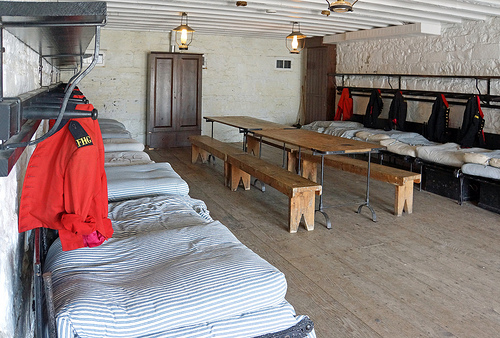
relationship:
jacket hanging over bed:
[15, 102, 112, 251] [32, 195, 296, 336]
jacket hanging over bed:
[17, 103, 112, 251] [301, 118, 361, 138]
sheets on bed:
[57, 200, 286, 333] [21, 189, 312, 337]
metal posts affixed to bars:
[337, 73, 347, 94] [329, 70, 499, 79]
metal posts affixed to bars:
[393, 71, 402, 93] [329, 70, 499, 79]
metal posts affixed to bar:
[482, 79, 495, 107] [336, 83, 499, 106]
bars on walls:
[329, 70, 499, 79] [1, 19, 498, 142]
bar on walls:
[336, 83, 499, 106] [1, 19, 498, 142]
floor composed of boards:
[232, 199, 499, 329] [148, 142, 498, 336]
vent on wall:
[86, 1, 483, 43] [61, 25, 303, 154]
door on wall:
[131, 39, 237, 159] [61, 25, 303, 154]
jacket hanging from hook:
[335, 88, 355, 122] [60, 105, 101, 123]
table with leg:
[183, 111, 383, 233] [308, 147, 335, 234]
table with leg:
[183, 111, 383, 233] [353, 145, 380, 224]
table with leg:
[183, 111, 383, 233] [241, 127, 271, 193]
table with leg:
[183, 111, 383, 233] [205, 115, 218, 162]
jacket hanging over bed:
[17, 103, 112, 251] [35, 194, 321, 334]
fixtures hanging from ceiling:
[169, 10, 311, 61] [71, 0, 498, 38]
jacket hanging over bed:
[15, 102, 112, 251] [43, 229, 308, 336]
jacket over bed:
[17, 103, 112, 251] [58, 195, 296, 335]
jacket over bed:
[335, 88, 355, 122] [58, 195, 296, 335]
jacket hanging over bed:
[335, 88, 354, 116] [305, 119, 364, 134]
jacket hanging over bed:
[17, 103, 112, 251] [32, 183, 287, 335]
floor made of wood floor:
[152, 147, 496, 338] [143, 141, 498, 336]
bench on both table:
[187, 135, 324, 235] [203, 112, 385, 227]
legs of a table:
[309, 159, 376, 226] [240, 112, 359, 202]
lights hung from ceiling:
[167, 10, 307, 55] [98, 0, 497, 41]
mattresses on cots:
[104, 165, 266, 326] [367, 128, 463, 163]